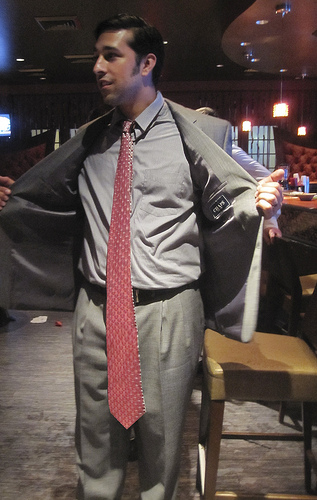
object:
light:
[294, 120, 310, 139]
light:
[269, 94, 292, 123]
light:
[239, 115, 253, 136]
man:
[0, 10, 285, 499]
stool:
[195, 322, 316, 499]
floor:
[0, 308, 316, 500]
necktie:
[104, 117, 147, 431]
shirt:
[65, 92, 205, 297]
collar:
[107, 90, 164, 140]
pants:
[68, 280, 206, 499]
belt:
[80, 272, 203, 304]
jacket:
[2, 93, 276, 344]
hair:
[91, 12, 165, 86]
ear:
[141, 51, 157, 76]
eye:
[104, 51, 122, 63]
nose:
[92, 56, 107, 76]